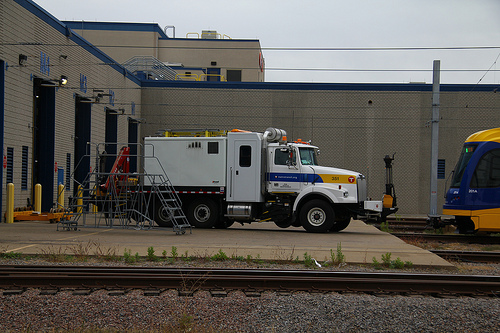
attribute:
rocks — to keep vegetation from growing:
[197, 297, 349, 332]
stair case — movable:
[93, 158, 189, 228]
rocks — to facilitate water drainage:
[0, 295, 498, 331]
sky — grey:
[287, 9, 499, 43]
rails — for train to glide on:
[202, 249, 443, 314]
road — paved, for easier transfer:
[205, 219, 465, 254]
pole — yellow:
[4, 183, 22, 225]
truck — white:
[137, 128, 389, 239]